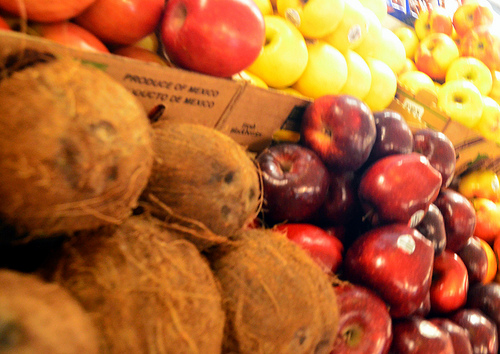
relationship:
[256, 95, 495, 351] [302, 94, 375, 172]
apple next to apple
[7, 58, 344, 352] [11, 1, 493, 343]
coconuts on fruit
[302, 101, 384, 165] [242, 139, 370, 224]
an apple next to apple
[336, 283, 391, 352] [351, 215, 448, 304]
apple next to apple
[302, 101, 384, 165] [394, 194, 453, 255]
an apple next to apple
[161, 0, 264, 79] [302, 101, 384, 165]
aplle next to an apple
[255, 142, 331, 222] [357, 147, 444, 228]
aplle next to aplle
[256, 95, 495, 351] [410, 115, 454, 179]
apple next to apple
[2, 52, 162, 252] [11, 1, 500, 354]
coconut on fruit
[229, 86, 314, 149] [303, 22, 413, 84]
box of apples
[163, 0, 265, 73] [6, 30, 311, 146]
apple in box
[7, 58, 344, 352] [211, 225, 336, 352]
coconuts on shells